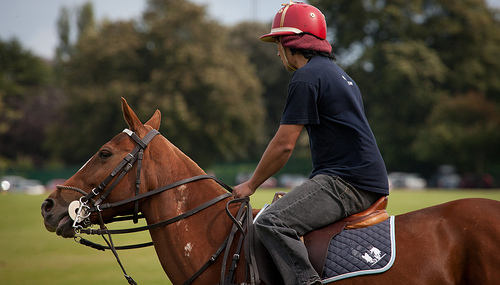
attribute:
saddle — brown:
[348, 194, 405, 230]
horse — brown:
[16, 72, 498, 281]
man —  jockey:
[230, 2, 390, 284]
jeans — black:
[245, 170, 390, 280]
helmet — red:
[253, 0, 329, 40]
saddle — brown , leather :
[248, 191, 390, 283]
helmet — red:
[258, 0, 327, 39]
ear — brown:
[117, 95, 140, 127]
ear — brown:
[138, 101, 175, 139]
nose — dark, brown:
[14, 190, 109, 227]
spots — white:
[181, 236, 198, 262]